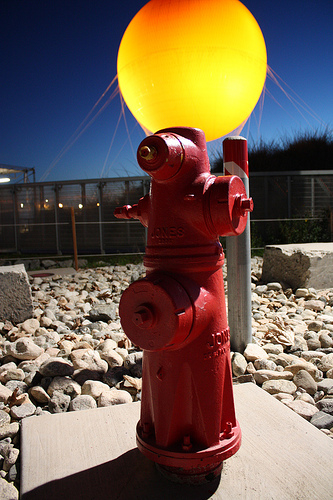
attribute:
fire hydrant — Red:
[111, 125, 245, 489]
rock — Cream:
[245, 342, 267, 362]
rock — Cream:
[306, 337, 321, 348]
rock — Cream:
[296, 286, 306, 296]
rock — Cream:
[265, 281, 283, 289]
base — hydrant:
[22, 386, 330, 479]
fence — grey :
[3, 168, 332, 265]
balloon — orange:
[123, 0, 262, 127]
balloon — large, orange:
[116, 0, 266, 142]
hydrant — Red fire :
[111, 127, 242, 472]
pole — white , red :
[219, 131, 259, 358]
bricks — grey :
[1, 243, 331, 322]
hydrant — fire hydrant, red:
[113, 126, 252, 485]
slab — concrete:
[22, 415, 160, 498]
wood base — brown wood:
[20, 382, 331, 498]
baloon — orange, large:
[115, 0, 269, 141]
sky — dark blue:
[2, 0, 114, 161]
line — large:
[119, 95, 141, 174]